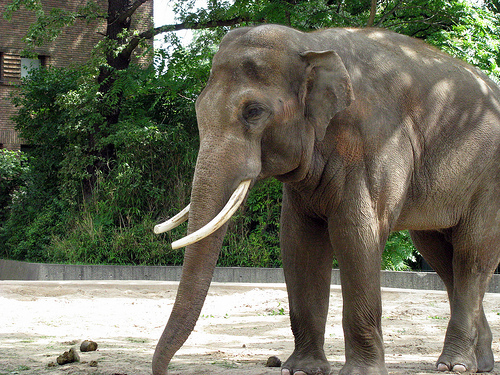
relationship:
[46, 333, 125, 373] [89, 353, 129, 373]
poop on ground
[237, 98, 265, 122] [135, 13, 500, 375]
eye of animal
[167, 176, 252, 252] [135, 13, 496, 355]
elephant tusks of animal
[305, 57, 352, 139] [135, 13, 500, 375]
ear of animal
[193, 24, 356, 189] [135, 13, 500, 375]
head of animal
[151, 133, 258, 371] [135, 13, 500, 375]
trunk of animal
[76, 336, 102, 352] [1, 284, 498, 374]
elephant poop on ground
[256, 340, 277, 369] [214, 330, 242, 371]
excrement on ground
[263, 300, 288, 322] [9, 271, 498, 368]
leaves on ground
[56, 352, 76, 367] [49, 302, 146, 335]
dung on ground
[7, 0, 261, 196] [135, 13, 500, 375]
tree behind animal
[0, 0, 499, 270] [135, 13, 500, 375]
tree behind animal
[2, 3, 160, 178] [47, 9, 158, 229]
building behind tree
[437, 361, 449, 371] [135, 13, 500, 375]
toe on animal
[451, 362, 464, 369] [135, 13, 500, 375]
toe on animal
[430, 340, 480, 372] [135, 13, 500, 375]
foot on animal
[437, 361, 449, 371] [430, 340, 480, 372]
toe on foot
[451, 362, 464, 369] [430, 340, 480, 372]
toe on foot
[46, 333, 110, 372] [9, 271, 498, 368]
poop on ground